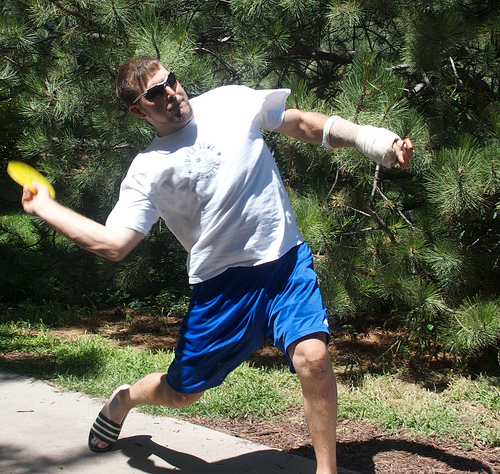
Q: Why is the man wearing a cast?
A: Injured his arm.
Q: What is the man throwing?
A: Frisbee.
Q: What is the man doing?
A: Throwing a frisbee.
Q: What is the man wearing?
A: Sunglasses.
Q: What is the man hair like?
A: Brown.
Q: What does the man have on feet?
A: Slipper.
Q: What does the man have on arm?
A: Cast.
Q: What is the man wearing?
A: Tee shirt.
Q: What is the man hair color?
A: Brown.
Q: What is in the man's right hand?
A: Yellow frisbee.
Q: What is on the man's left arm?
A: White cast.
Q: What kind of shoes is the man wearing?
A: Black and white flip flops.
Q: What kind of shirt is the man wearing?
A: White shirt with circular design on front.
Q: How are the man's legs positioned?
A: Left leg in front of right leg.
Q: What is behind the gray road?
A: Patches of grass and dirt.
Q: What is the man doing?
A: Throwing a frisbee.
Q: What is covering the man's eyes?
A: Black sunglasses with white frames.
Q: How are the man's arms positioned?
A: Left arm stretched out, right arm in back.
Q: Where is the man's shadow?
A: On gray concrete and dirt patch.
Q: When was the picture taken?
A: Daytime.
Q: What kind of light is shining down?
A: Sunlight.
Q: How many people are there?
A: One.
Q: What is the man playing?
A: Frisbee.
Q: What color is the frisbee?
A: Yellow.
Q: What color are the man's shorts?
A: Blue.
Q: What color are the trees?
A: Green.